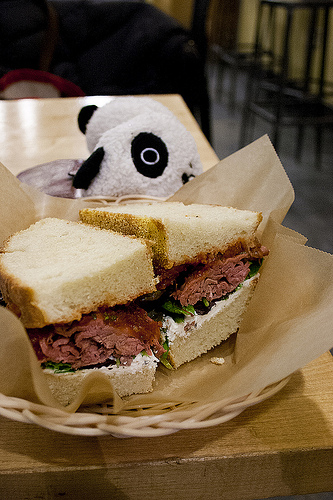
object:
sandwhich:
[0, 216, 156, 407]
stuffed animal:
[75, 95, 203, 197]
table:
[0, 94, 333, 499]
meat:
[179, 259, 248, 305]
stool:
[255, 0, 328, 167]